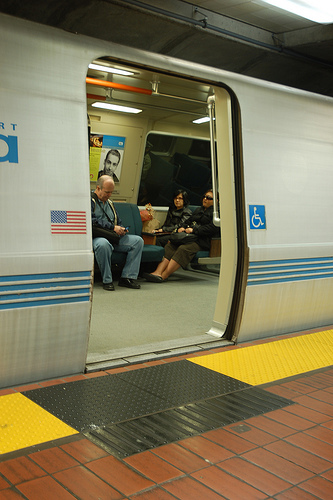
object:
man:
[91, 175, 144, 292]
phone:
[124, 225, 130, 234]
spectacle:
[96, 186, 114, 197]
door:
[85, 54, 247, 371]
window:
[137, 131, 220, 207]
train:
[1, 9, 333, 388]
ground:
[0, 323, 332, 500]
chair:
[92, 202, 165, 281]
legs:
[161, 240, 195, 281]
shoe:
[118, 279, 141, 288]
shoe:
[104, 281, 117, 290]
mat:
[18, 357, 296, 461]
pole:
[207, 95, 223, 227]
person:
[147, 188, 220, 282]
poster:
[89, 132, 126, 185]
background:
[0, 0, 333, 500]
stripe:
[1, 269, 94, 283]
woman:
[152, 190, 196, 236]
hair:
[167, 190, 188, 213]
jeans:
[93, 234, 144, 283]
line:
[0, 387, 80, 457]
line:
[187, 327, 333, 387]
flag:
[52, 211, 89, 234]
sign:
[250, 203, 268, 230]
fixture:
[92, 101, 143, 116]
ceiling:
[0, 0, 333, 99]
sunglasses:
[202, 195, 214, 202]